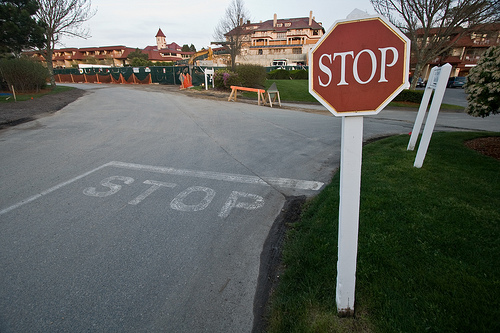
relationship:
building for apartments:
[141, 27, 188, 61] [51, 46, 121, 58]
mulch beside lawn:
[466, 136, 500, 153] [398, 191, 496, 294]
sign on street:
[303, 13, 418, 115] [152, 113, 316, 163]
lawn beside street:
[398, 191, 496, 294] [152, 113, 316, 163]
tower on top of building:
[154, 28, 167, 49] [141, 27, 188, 61]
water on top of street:
[256, 255, 269, 273] [152, 113, 316, 163]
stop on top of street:
[85, 166, 267, 223] [152, 113, 316, 163]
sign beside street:
[303, 13, 418, 115] [152, 113, 316, 163]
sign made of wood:
[303, 13, 418, 115] [330, 119, 368, 303]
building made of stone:
[224, 19, 318, 47] [247, 55, 270, 68]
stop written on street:
[85, 166, 267, 223] [152, 113, 316, 163]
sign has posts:
[406, 63, 455, 169] [409, 95, 445, 170]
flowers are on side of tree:
[469, 67, 482, 78] [467, 49, 500, 113]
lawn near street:
[398, 191, 496, 294] [152, 113, 316, 163]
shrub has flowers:
[211, 66, 245, 92] [223, 71, 231, 87]